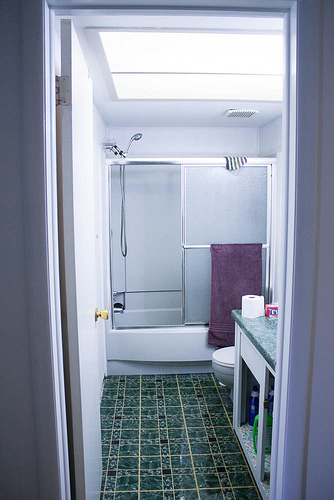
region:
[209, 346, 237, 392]
part of the white toilet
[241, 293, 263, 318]
a white roll of toilet paper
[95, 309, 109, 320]
the gold handle of the door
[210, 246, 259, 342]
a large wine color towel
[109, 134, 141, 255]
the metallic shower faucet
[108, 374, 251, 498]
a floor with green tiles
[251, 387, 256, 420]
the blue toilet cleaner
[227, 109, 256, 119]
the extractor of the bathtub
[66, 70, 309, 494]
a ordered clean bathroom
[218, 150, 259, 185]
black and white striped rag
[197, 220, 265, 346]
purple towel hanging on rod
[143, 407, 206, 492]
green marble tiled floor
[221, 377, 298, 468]
cabinet under sink without doors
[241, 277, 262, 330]
white toilet rool on counter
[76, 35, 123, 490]
white door with gold knob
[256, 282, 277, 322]
red and blue box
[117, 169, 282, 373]
shower door opened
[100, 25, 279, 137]
two long ceiling recess square lights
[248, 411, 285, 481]
items underneath bathroom cabinet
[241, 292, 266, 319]
roll of toilet paper on the counter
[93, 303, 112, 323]
door knob on a white door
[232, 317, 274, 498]
cabinet with no door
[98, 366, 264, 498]
green floor in the bathroom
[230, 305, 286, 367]
green counter in the bathroom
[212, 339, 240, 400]
white toilet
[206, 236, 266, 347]
towel hanging on the shower door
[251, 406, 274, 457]
green bottle under the sink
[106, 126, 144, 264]
silver shower attachment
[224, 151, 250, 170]
striped wash cloth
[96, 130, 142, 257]
Chrome finish telephone shower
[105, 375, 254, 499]
Green laminated flooring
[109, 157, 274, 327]
Shower door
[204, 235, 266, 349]
Purple towel on the door handle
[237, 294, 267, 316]
Toilet paper roll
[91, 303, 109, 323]
Golden door knob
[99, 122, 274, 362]
Enclosed bathtub with sliding glass door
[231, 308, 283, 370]
Green countertop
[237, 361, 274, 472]
Cleaning supplies below the sink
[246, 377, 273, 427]
Blue toilet bowl cleaners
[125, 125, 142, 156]
the shoer head in the shower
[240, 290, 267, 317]
toilet paper roll on the counter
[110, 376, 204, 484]
the green bathroom tile floor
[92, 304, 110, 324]
the handle of the bathroom door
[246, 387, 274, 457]
cleaning products under the sink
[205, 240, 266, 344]
the towle hanging down from the rack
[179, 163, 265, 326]
the shower door on the track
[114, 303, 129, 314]
the nozzel for the bath tub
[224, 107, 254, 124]
a vent on the ceiling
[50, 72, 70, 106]
the bracket on the door of the bathroom